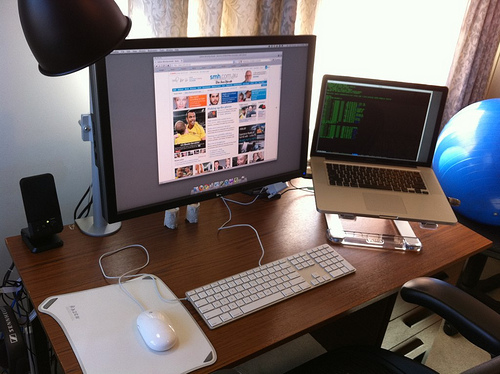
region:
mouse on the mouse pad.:
[140, 310, 174, 348]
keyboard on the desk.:
[200, 249, 347, 340]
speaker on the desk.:
[24, 165, 57, 247]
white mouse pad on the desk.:
[70, 306, 117, 346]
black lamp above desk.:
[42, 5, 119, 55]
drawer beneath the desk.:
[398, 317, 430, 343]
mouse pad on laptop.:
[370, 196, 402, 209]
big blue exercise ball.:
[455, 127, 487, 184]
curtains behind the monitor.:
[169, 7, 293, 24]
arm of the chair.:
[417, 287, 484, 332]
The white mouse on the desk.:
[134, 310, 181, 352]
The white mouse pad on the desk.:
[39, 285, 211, 371]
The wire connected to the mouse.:
[87, 235, 181, 306]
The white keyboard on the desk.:
[172, 240, 359, 326]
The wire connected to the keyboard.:
[220, 187, 282, 261]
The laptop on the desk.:
[315, 62, 454, 221]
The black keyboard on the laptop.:
[327, 153, 437, 194]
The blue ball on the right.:
[442, 86, 499, 218]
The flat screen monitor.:
[95, 52, 309, 199]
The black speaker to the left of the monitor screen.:
[16, 165, 76, 260]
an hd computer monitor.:
[81, 30, 323, 241]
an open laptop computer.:
[306, 74, 465, 229]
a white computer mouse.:
[132, 305, 185, 360]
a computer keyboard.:
[169, 231, 351, 361]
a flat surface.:
[39, 271, 227, 370]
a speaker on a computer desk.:
[19, 157, 66, 259]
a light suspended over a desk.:
[14, 0, 144, 82]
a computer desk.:
[0, 160, 494, 370]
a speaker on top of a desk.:
[15, 159, 87, 273]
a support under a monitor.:
[177, 194, 209, 234]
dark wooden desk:
[6, 166, 492, 371]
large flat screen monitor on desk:
[85, 32, 307, 217]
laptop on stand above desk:
[307, 70, 457, 225]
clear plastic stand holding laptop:
[320, 205, 420, 247]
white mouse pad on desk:
[30, 270, 215, 370]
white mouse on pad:
[132, 305, 177, 350]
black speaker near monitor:
[15, 167, 60, 254]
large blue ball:
[432, 95, 492, 215]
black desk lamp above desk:
[12, 0, 132, 77]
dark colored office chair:
[258, 275, 496, 371]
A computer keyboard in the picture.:
[185, 244, 356, 306]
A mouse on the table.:
[135, 308, 184, 356]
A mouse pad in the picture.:
[67, 309, 124, 353]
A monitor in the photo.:
[97, 65, 288, 220]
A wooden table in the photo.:
[358, 260, 406, 301]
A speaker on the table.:
[17, 158, 67, 258]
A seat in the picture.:
[317, 340, 424, 371]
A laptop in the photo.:
[337, 74, 434, 212]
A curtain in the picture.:
[455, 22, 491, 89]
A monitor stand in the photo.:
[82, 192, 105, 234]